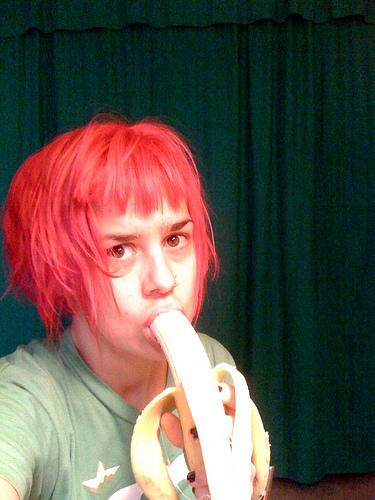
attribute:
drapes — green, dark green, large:
[1, 0, 374, 474]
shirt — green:
[0, 333, 278, 500]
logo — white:
[83, 450, 192, 500]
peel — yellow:
[116, 386, 183, 498]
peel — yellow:
[220, 359, 264, 499]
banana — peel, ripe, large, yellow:
[143, 307, 248, 500]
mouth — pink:
[138, 304, 192, 344]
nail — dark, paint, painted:
[183, 466, 205, 487]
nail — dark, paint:
[187, 425, 201, 446]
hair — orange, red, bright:
[5, 112, 221, 339]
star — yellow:
[71, 450, 126, 498]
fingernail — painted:
[185, 420, 204, 443]